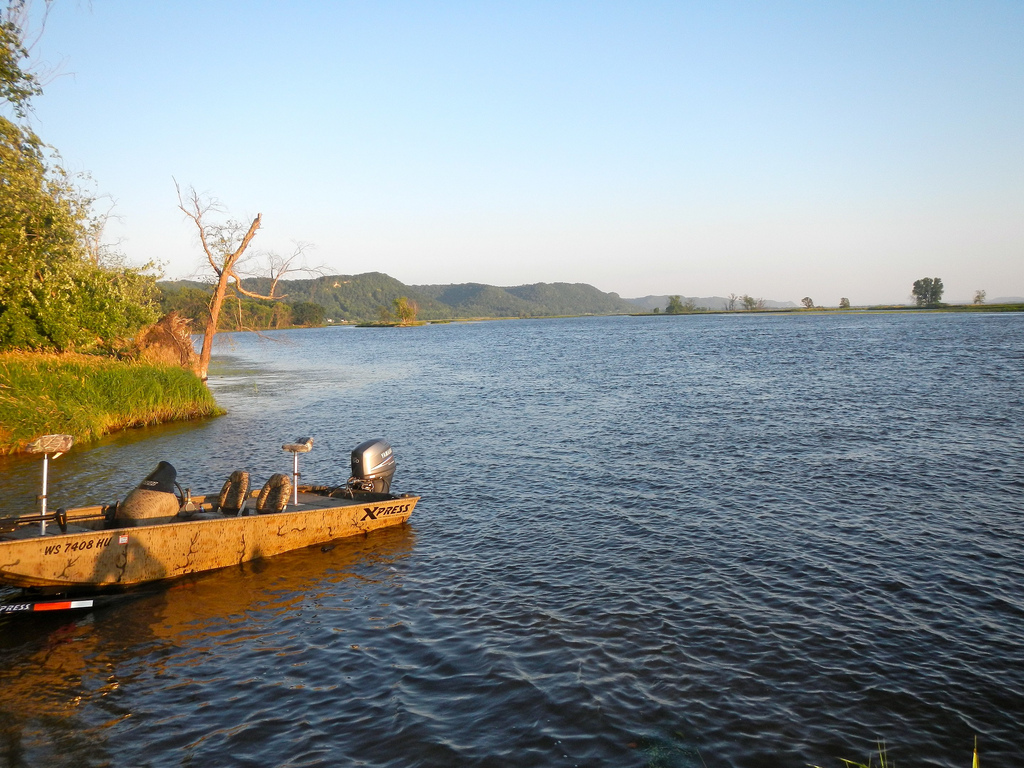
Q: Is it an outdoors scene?
A: Yes, it is outdoors.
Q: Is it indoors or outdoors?
A: It is outdoors.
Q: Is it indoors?
A: No, it is outdoors.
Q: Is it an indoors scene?
A: No, it is outdoors.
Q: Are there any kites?
A: No, there are no kites.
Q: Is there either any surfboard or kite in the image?
A: No, there are no kites or surfboards.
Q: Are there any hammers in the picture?
A: No, there are no hammers.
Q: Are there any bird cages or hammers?
A: No, there are no hammers or bird cages.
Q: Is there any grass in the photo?
A: Yes, there is grass.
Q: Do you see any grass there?
A: Yes, there is grass.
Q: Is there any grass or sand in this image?
A: Yes, there is grass.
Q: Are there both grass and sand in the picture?
A: No, there is grass but no sand.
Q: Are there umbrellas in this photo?
A: No, there are no umbrellas.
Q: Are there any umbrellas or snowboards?
A: No, there are no umbrellas or snowboards.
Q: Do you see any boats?
A: Yes, there is a boat.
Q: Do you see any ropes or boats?
A: Yes, there is a boat.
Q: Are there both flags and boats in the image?
A: No, there is a boat but no flags.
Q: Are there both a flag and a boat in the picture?
A: No, there is a boat but no flags.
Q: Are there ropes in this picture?
A: No, there are no ropes.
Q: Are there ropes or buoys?
A: No, there are no ropes or buoys.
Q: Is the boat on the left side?
A: Yes, the boat is on the left of the image.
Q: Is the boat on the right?
A: No, the boat is on the left of the image.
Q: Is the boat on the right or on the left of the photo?
A: The boat is on the left of the image.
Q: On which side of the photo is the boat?
A: The boat is on the left of the image.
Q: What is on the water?
A: The boat is on the water.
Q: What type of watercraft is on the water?
A: The watercraft is a boat.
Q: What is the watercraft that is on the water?
A: The watercraft is a boat.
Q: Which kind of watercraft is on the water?
A: The watercraft is a boat.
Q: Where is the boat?
A: The boat is on the water.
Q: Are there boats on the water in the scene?
A: Yes, there is a boat on the water.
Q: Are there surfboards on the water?
A: No, there is a boat on the water.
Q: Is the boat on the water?
A: Yes, the boat is on the water.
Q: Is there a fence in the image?
A: No, there are no fences.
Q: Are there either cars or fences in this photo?
A: No, there are no fences or cars.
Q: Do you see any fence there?
A: No, there are no fences.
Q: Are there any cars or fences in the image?
A: No, there are no fences or cars.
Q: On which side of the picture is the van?
A: The van is on the right of the image.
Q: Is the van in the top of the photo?
A: No, the van is in the bottom of the image.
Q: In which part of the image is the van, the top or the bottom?
A: The van is in the bottom of the image.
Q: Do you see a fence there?
A: No, there are no fences.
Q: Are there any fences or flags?
A: No, there are no fences or flags.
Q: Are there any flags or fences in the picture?
A: No, there are no fences or flags.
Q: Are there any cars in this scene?
A: No, there are no cars.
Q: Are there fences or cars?
A: No, there are no cars or fences.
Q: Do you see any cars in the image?
A: No, there are no cars.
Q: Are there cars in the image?
A: No, there are no cars.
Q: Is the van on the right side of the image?
A: Yes, the van is on the right of the image.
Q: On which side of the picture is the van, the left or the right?
A: The van is on the right of the image.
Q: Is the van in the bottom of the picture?
A: Yes, the van is in the bottom of the image.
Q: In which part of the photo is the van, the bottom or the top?
A: The van is in the bottom of the image.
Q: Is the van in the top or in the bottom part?
A: The van is in the bottom of the image.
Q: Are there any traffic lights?
A: No, there are no traffic lights.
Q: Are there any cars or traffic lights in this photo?
A: No, there are no traffic lights or cars.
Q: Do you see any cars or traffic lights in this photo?
A: No, there are no traffic lights or cars.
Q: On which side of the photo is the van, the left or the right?
A: The van is on the right of the image.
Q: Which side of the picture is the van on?
A: The van is on the right of the image.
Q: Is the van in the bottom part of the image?
A: Yes, the van is in the bottom of the image.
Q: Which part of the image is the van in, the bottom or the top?
A: The van is in the bottom of the image.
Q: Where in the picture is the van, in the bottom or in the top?
A: The van is in the bottom of the image.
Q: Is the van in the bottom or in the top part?
A: The van is in the bottom of the image.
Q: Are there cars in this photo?
A: No, there are no cars.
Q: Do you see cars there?
A: No, there are no cars.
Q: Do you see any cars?
A: No, there are no cars.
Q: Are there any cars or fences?
A: No, there are no cars or fences.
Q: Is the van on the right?
A: Yes, the van is on the right of the image.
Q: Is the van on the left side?
A: No, the van is on the right of the image.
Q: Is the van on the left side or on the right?
A: The van is on the right of the image.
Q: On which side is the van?
A: The van is on the right of the image.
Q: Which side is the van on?
A: The van is on the right of the image.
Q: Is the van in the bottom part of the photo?
A: Yes, the van is in the bottom of the image.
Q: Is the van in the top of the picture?
A: No, the van is in the bottom of the image.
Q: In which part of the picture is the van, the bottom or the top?
A: The van is in the bottom of the image.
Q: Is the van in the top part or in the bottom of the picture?
A: The van is in the bottom of the image.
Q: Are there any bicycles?
A: No, there are no bicycles.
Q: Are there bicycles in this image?
A: No, there are no bicycles.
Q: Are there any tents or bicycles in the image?
A: No, there are no bicycles or tents.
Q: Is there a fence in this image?
A: No, there are no fences.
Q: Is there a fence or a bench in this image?
A: No, there are no fences or benches.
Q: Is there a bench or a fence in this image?
A: No, there are no fences or benches.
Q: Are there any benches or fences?
A: No, there are no fences or benches.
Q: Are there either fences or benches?
A: No, there are no fences or benches.